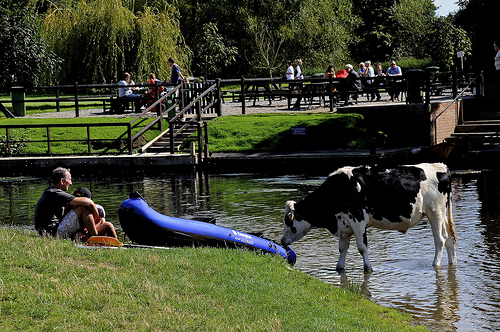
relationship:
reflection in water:
[391, 260, 436, 271] [324, 229, 499, 329]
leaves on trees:
[32, 17, 81, 48] [244, 21, 287, 73]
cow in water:
[281, 162, 456, 274] [0, 172, 500, 330]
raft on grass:
[113, 186, 306, 268] [0, 221, 436, 330]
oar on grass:
[85, 232, 171, 251] [0, 221, 436, 330]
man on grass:
[34, 166, 100, 239] [0, 221, 436, 330]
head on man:
[48, 161, 71, 188] [30, 159, 104, 237]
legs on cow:
[424, 203, 459, 267] [275, 161, 467, 272]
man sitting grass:
[35, 159, 81, 231] [105, 272, 172, 325]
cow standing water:
[281, 162, 456, 274] [309, 238, 498, 323]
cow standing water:
[281, 162, 456, 274] [214, 176, 294, 239]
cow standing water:
[281, 162, 456, 274] [451, 157, 498, 303]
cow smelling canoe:
[275, 161, 467, 272] [116, 185, 297, 269]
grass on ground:
[0, 221, 436, 330] [18, 216, 409, 328]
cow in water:
[281, 162, 456, 274] [5, 166, 499, 318]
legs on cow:
[336, 214, 375, 273] [273, 149, 470, 277]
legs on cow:
[336, 214, 375, 273] [277, 157, 477, 279]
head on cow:
[276, 195, 317, 251] [275, 161, 467, 272]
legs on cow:
[334, 214, 386, 300] [271, 140, 478, 285]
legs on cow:
[427, 210, 459, 270] [275, 161, 467, 272]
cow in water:
[281, 162, 456, 274] [344, 224, 478, 315]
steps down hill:
[157, 110, 194, 159] [15, 107, 460, 156]